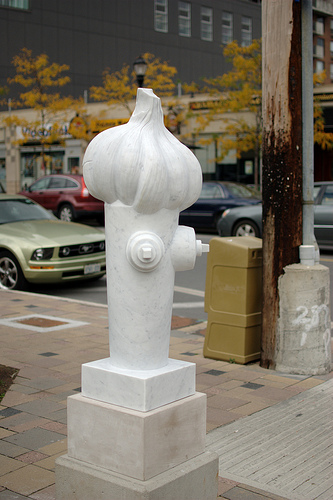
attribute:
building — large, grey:
[2, 0, 259, 91]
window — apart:
[177, 0, 190, 37]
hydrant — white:
[51, 87, 219, 498]